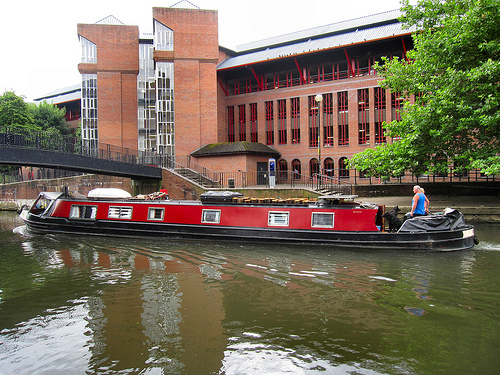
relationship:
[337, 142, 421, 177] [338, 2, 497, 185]
leaves on tree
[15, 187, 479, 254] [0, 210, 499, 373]
boat in water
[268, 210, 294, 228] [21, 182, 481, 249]
window of boat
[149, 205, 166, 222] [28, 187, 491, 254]
window of boat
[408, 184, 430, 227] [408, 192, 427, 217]
man wearing blue top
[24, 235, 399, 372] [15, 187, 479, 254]
reflection of boat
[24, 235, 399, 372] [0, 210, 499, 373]
reflection in water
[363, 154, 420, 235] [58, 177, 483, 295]
dogs riding in boat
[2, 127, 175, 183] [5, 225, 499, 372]
bridge that goes over lake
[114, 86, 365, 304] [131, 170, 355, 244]
windows framed on boat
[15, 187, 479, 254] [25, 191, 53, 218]
boat front with open windows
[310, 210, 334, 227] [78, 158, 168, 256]
window in side of boat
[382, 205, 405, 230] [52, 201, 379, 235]
black dog on deck of boat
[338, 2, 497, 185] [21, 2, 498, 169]
tree next to building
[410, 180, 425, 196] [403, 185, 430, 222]
head of man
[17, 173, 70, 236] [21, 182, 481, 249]
cabin area of boat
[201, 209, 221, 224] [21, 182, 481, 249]
window of boat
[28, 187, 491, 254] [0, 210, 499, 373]
boat reflected on water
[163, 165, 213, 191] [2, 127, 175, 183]
steps to bridge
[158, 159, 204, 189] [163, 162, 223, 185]
rails on stairs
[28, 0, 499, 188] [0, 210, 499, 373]
building next to water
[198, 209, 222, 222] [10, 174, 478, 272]
window on boat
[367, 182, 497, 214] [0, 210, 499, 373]
pavement near water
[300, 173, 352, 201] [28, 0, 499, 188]
steps near building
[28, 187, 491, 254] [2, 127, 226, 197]
boat under bridge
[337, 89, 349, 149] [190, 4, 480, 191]
window on garage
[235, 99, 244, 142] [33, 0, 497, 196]
window on garage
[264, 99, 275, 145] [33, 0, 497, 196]
window on garage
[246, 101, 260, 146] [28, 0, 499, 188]
window on building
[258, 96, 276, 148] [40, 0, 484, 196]
window on parking garage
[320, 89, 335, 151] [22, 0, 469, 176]
window on parking garage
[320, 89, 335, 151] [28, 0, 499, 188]
window on building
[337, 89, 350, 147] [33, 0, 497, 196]
window on garage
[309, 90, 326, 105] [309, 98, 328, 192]
light on back of post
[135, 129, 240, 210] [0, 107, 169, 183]
stairs leading to bridge